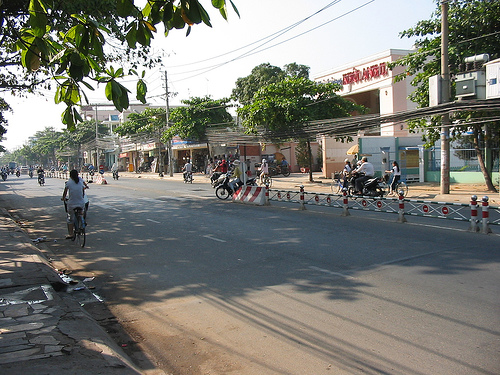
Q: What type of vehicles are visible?
A: Bikes.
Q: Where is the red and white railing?
A: Right of the street.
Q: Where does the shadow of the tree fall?
A: On the street in front.,.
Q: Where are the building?
A: On the right.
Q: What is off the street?
A: Sidewalk.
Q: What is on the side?
A: A strip of stores.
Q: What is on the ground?
A: Shadows of trees.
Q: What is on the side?
A: Trees.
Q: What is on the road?
A: Shadows of electric lines.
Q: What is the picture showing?
A: People riding bikes.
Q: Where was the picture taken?
A: On the street.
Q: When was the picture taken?
A: During the day.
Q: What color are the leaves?
A: Green.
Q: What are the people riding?
A: Bikes.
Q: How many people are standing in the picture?
A: None.